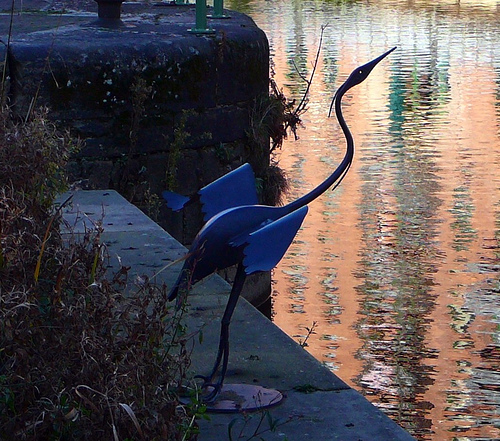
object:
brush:
[0, 0, 328, 441]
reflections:
[188, 0, 500, 441]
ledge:
[163, 162, 308, 311]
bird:
[167, 46, 398, 404]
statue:
[165, 46, 397, 412]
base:
[178, 384, 284, 413]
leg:
[184, 262, 248, 406]